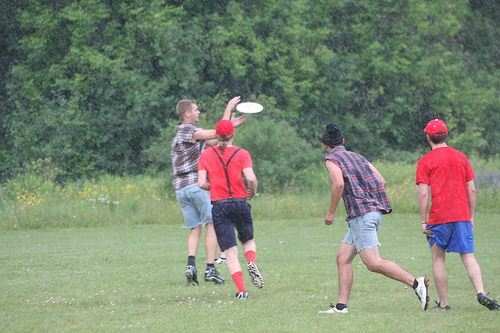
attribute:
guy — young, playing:
[166, 94, 230, 284]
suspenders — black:
[211, 148, 242, 204]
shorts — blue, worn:
[428, 214, 476, 262]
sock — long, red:
[224, 265, 250, 292]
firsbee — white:
[233, 95, 275, 122]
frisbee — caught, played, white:
[222, 82, 276, 120]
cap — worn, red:
[208, 106, 236, 139]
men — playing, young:
[153, 107, 490, 333]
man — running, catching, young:
[210, 112, 282, 278]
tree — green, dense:
[67, 43, 353, 83]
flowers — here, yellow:
[13, 176, 128, 226]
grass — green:
[40, 238, 175, 300]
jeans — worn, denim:
[342, 205, 397, 252]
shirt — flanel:
[322, 136, 386, 236]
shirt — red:
[200, 147, 261, 227]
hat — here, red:
[422, 116, 451, 137]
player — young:
[307, 123, 444, 314]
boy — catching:
[309, 117, 434, 324]